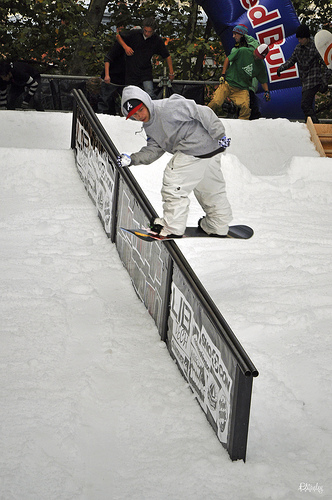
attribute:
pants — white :
[162, 150, 239, 210]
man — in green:
[212, 48, 264, 120]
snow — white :
[259, 148, 284, 196]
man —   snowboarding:
[116, 84, 231, 236]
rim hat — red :
[117, 103, 153, 119]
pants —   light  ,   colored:
[159, 154, 232, 239]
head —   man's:
[105, 85, 162, 130]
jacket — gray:
[120, 86, 232, 169]